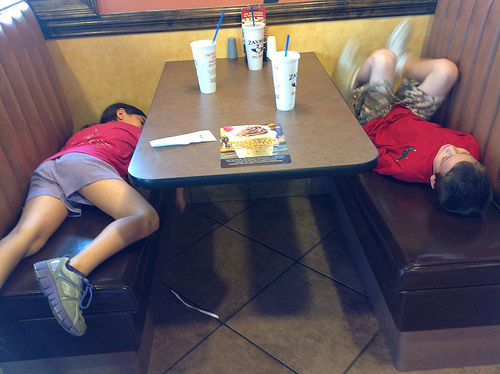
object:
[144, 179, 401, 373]
ground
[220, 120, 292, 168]
menu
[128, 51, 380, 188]
brown table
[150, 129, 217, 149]
receipt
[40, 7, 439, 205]
wall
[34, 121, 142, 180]
shirt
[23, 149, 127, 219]
shorts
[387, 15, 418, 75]
shoes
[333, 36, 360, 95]
shoes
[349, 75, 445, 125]
shorts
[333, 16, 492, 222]
boy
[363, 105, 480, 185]
red shirt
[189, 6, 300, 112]
plants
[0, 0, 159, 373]
seat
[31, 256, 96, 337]
shoe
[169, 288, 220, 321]
paper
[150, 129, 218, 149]
napkin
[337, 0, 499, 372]
booth bench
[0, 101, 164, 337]
child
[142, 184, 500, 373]
floor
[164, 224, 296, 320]
brown tile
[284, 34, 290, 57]
straw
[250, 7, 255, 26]
straw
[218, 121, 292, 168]
advertisement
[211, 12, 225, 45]
straw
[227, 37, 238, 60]
pepper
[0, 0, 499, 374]
booth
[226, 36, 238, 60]
shaker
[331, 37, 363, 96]
foot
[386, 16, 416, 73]
foot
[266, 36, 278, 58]
salt shaker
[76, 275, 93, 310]
laces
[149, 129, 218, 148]
bill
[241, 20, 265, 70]
cup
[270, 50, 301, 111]
cup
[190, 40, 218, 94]
cup